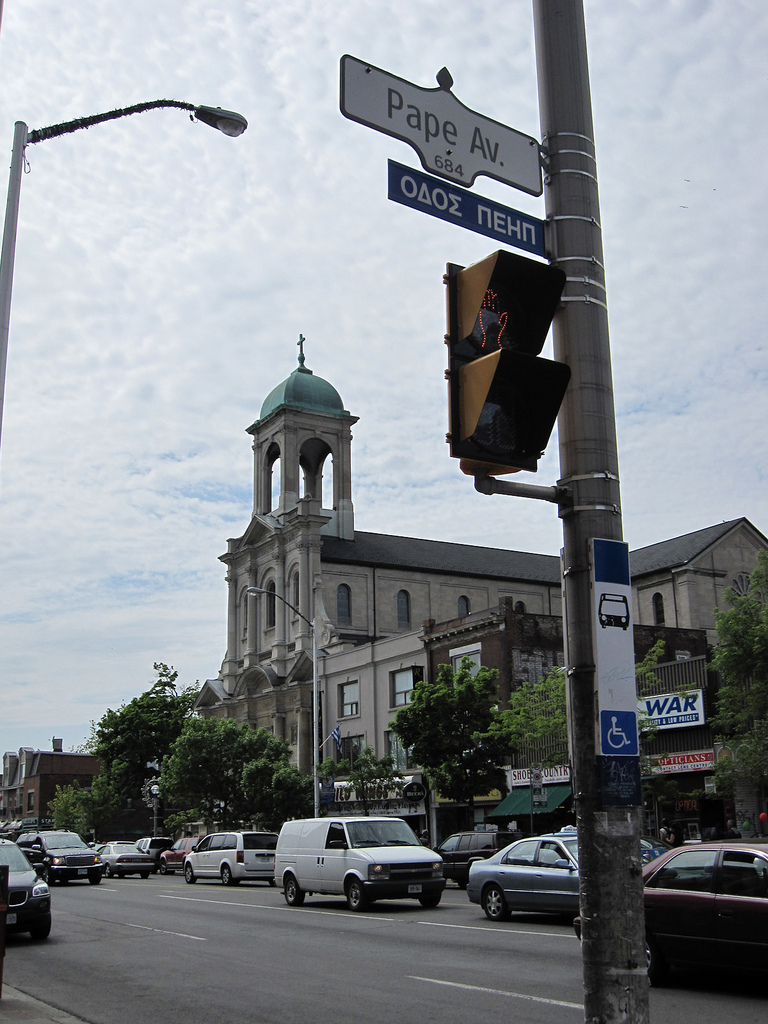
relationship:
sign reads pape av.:
[331, 50, 548, 195] [378, 92, 509, 175]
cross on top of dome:
[289, 332, 322, 376] [253, 369, 350, 433]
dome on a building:
[258, 369, 347, 430] [219, 369, 766, 782]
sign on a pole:
[378, 165, 562, 248] [521, 9, 680, 1022]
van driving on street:
[261, 813, 448, 916] [12, 857, 763, 1021]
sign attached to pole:
[588, 525, 649, 754] [526, 9, 662, 1022]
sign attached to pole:
[338, 55, 544, 202] [526, 9, 662, 1022]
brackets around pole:
[546, 159, 604, 189] [540, 11, 660, 1021]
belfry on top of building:
[244, 327, 358, 528] [191, 336, 766, 853]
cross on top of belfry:
[297, 334, 305, 354] [239, 369, 370, 536]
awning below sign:
[484, 783, 571, 819] [498, 754, 570, 793]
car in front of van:
[465, 821, 635, 924] [269, 807, 450, 913]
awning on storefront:
[479, 785, 582, 821] [487, 754, 576, 862]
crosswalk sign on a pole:
[431, 240, 570, 482] [532, 0, 654, 1024]